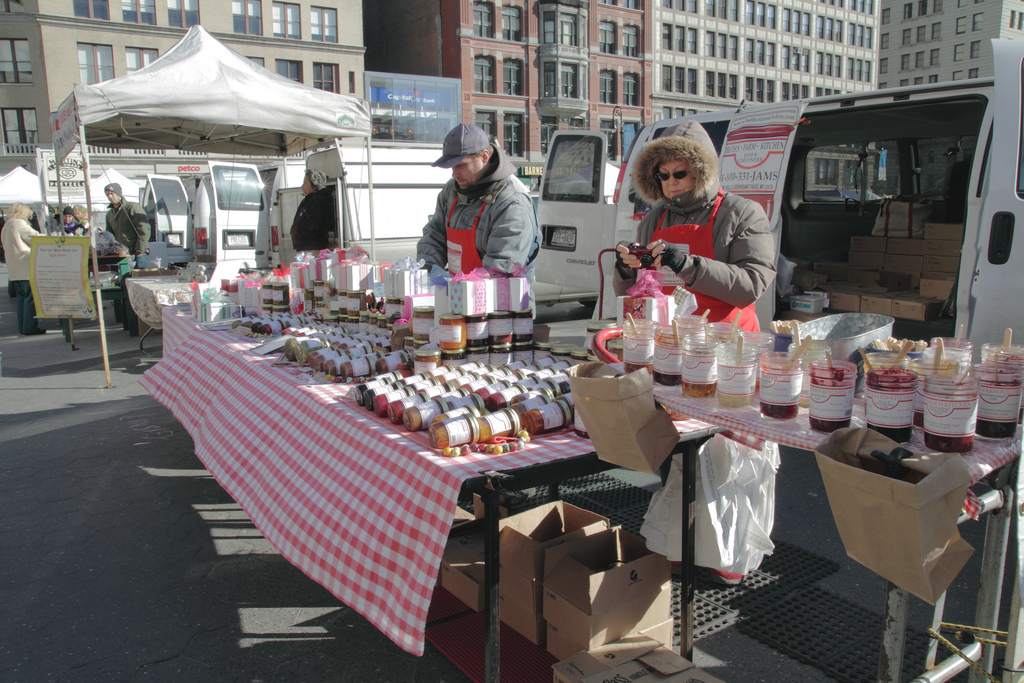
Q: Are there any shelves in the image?
A: No, there are no shelves.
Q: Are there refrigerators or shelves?
A: No, there are no shelves or refrigerators.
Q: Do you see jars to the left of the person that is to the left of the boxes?
A: Yes, there is a jar to the left of the person.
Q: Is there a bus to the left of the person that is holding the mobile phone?
A: No, there is a jar to the left of the person.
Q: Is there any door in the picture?
A: Yes, there is a door.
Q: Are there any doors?
A: Yes, there is a door.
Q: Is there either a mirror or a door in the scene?
A: Yes, there is a door.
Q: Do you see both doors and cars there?
A: No, there is a door but no cars.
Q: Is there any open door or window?
A: Yes, there is an open door.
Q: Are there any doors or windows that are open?
A: Yes, the door is open.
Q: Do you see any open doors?
A: Yes, there is an open door.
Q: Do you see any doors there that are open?
A: Yes, there is a door that is open.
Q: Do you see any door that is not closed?
A: Yes, there is a open door.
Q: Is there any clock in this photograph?
A: No, there are no clocks.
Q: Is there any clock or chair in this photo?
A: No, there are no clocks or chairs.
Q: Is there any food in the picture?
A: Yes, there is food.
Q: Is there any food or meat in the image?
A: Yes, there is food.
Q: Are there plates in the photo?
A: No, there are no plates.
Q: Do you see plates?
A: No, there are no plates.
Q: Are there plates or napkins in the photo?
A: No, there are no plates or napkins.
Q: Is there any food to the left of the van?
A: Yes, there is food to the left of the van.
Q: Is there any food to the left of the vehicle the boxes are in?
A: Yes, there is food to the left of the van.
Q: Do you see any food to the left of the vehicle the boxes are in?
A: Yes, there is food to the left of the van.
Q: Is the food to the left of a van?
A: Yes, the food is to the left of a van.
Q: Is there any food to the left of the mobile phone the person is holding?
A: Yes, there is food to the left of the mobile phone.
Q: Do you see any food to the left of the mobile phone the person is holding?
A: Yes, there is food to the left of the mobile phone.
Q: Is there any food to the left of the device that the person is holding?
A: Yes, there is food to the left of the mobile phone.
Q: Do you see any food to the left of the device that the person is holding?
A: Yes, there is food to the left of the mobile phone.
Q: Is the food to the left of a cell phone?
A: Yes, the food is to the left of a cell phone.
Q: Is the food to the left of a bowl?
A: No, the food is to the left of a cell phone.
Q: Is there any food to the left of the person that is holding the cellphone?
A: Yes, there is food to the left of the person.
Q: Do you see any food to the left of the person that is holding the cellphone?
A: Yes, there is food to the left of the person.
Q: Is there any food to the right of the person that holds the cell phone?
A: No, the food is to the left of the person.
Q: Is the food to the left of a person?
A: Yes, the food is to the left of a person.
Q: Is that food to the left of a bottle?
A: No, the food is to the left of a person.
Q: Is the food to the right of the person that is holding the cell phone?
A: No, the food is to the left of the person.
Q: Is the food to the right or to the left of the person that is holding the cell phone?
A: The food is to the left of the person.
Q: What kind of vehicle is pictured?
A: The vehicle is a van.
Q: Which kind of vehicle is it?
A: The vehicle is a van.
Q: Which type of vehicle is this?
A: This is a van.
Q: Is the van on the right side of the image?
A: Yes, the van is on the right of the image.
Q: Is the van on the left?
A: No, the van is on the right of the image.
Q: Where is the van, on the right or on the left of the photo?
A: The van is on the right of the image.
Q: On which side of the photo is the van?
A: The van is on the right of the image.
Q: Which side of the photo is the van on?
A: The van is on the right of the image.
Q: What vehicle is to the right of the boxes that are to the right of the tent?
A: The vehicle is a van.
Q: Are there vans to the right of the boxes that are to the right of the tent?
A: Yes, there is a van to the right of the boxes.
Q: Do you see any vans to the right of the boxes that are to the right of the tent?
A: Yes, there is a van to the right of the boxes.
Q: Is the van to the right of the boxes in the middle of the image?
A: Yes, the van is to the right of the boxes.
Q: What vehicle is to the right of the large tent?
A: The vehicle is a van.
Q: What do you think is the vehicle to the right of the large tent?
A: The vehicle is a van.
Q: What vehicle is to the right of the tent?
A: The vehicle is a van.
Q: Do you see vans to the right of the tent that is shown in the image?
A: Yes, there is a van to the right of the tent.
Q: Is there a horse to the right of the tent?
A: No, there is a van to the right of the tent.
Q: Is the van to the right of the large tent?
A: Yes, the van is to the right of the tent.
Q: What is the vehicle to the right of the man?
A: The vehicle is a van.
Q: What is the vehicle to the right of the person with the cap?
A: The vehicle is a van.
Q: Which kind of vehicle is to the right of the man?
A: The vehicle is a van.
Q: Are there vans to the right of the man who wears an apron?
A: Yes, there is a van to the right of the man.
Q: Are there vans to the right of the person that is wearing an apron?
A: Yes, there is a van to the right of the man.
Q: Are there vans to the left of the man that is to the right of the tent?
A: No, the van is to the right of the man.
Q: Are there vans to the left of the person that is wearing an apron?
A: No, the van is to the right of the man.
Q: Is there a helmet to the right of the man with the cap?
A: No, there is a van to the right of the man.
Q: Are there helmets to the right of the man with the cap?
A: No, there is a van to the right of the man.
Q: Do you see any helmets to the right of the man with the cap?
A: No, there is a van to the right of the man.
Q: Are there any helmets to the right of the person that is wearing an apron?
A: No, there is a van to the right of the man.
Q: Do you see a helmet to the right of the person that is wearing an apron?
A: No, there is a van to the right of the man.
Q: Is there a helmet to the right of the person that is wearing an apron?
A: No, there is a van to the right of the man.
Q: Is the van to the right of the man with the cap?
A: Yes, the van is to the right of the man.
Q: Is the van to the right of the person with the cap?
A: Yes, the van is to the right of the man.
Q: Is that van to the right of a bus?
A: No, the van is to the right of the man.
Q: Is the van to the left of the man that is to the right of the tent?
A: No, the van is to the right of the man.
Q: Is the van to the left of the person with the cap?
A: No, the van is to the right of the man.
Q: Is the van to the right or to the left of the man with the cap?
A: The van is to the right of the man.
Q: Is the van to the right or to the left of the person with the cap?
A: The van is to the right of the man.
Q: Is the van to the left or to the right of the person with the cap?
A: The van is to the right of the man.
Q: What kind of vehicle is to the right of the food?
A: The vehicle is a van.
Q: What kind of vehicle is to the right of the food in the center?
A: The vehicle is a van.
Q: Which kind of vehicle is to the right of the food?
A: The vehicle is a van.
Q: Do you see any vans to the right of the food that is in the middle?
A: Yes, there is a van to the right of the food.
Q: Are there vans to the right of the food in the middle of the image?
A: Yes, there is a van to the right of the food.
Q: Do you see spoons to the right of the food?
A: No, there is a van to the right of the food.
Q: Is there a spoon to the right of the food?
A: No, there is a van to the right of the food.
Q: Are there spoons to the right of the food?
A: No, there is a van to the right of the food.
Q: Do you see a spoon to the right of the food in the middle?
A: No, there is a van to the right of the food.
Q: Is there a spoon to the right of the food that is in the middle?
A: No, there is a van to the right of the food.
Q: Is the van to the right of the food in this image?
A: Yes, the van is to the right of the food.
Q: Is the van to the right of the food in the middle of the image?
A: Yes, the van is to the right of the food.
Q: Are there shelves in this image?
A: No, there are no shelves.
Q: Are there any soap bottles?
A: No, there are no soap bottles.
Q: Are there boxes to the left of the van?
A: Yes, there are boxes to the left of the van.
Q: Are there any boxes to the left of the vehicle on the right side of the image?
A: Yes, there are boxes to the left of the van.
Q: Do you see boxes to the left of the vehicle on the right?
A: Yes, there are boxes to the left of the van.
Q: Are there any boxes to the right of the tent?
A: Yes, there are boxes to the right of the tent.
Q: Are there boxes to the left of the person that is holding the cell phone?
A: Yes, there are boxes to the left of the person.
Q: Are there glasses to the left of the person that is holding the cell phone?
A: No, there are boxes to the left of the person.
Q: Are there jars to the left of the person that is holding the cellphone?
A: Yes, there is a jar to the left of the person.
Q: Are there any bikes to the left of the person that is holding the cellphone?
A: No, there is a jar to the left of the person.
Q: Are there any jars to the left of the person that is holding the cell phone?
A: Yes, there is a jar to the left of the person.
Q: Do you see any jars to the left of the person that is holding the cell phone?
A: Yes, there is a jar to the left of the person.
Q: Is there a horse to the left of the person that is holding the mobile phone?
A: No, there is a jar to the left of the person.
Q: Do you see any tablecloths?
A: Yes, there is a tablecloth.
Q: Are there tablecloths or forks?
A: Yes, there is a tablecloth.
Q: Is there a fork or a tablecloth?
A: Yes, there is a tablecloth.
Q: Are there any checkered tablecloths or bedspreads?
A: Yes, there is a checkered tablecloth.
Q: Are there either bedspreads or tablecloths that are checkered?
A: Yes, the tablecloth is checkered.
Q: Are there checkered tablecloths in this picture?
A: Yes, there is a checkered tablecloth.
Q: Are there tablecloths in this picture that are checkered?
A: Yes, there is a tablecloth that is checkered.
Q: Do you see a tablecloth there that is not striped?
A: Yes, there is a checkered tablecloth.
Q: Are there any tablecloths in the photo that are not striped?
A: Yes, there is a checkered tablecloth.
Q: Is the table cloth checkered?
A: Yes, the table cloth is checkered.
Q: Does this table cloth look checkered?
A: Yes, the table cloth is checkered.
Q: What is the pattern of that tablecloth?
A: The tablecloth is checkered.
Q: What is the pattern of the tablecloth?
A: The tablecloth is checkered.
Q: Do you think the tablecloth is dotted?
A: No, the tablecloth is checkered.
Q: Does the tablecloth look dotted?
A: No, the tablecloth is checkered.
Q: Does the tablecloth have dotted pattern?
A: No, the tablecloth is checkered.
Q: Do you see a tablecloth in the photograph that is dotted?
A: No, there is a tablecloth but it is checkered.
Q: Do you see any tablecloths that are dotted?
A: No, there is a tablecloth but it is checkered.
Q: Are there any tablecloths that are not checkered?
A: No, there is a tablecloth but it is checkered.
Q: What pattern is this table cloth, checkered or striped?
A: The table cloth is checkered.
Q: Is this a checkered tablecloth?
A: Yes, this is a checkered tablecloth.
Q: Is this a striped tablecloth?
A: No, this is a checkered tablecloth.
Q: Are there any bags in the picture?
A: Yes, there is a bag.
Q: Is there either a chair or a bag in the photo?
A: Yes, there is a bag.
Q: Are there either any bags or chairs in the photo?
A: Yes, there is a bag.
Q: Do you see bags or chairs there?
A: Yes, there is a bag.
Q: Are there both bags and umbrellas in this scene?
A: No, there is a bag but no umbrellas.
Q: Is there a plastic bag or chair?
A: Yes, there is a plastic bag.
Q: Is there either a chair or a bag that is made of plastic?
A: Yes, the bag is made of plastic.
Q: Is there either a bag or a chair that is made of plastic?
A: Yes, the bag is made of plastic.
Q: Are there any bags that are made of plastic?
A: Yes, there is a bag that is made of plastic.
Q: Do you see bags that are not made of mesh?
A: Yes, there is a bag that is made of plastic.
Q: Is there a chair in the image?
A: No, there are no chairs.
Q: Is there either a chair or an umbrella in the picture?
A: No, there are no chairs or umbrellas.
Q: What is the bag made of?
A: The bag is made of plastic.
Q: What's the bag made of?
A: The bag is made of plastic.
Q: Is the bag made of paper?
A: No, the bag is made of plastic.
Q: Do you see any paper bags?
A: No, there is a bag but it is made of plastic.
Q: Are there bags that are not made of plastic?
A: No, there is a bag but it is made of plastic.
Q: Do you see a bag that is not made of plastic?
A: No, there is a bag but it is made of plastic.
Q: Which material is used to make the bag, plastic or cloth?
A: The bag is made of plastic.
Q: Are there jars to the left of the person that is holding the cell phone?
A: Yes, there is a jar to the left of the person.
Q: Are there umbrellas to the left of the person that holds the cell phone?
A: No, there is a jar to the left of the person.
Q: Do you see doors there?
A: Yes, there is a door.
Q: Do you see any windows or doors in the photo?
A: Yes, there is a door.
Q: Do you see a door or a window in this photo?
A: Yes, there is a door.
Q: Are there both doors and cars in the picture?
A: No, there is a door but no cars.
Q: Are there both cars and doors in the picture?
A: No, there is a door but no cars.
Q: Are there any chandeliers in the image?
A: No, there are no chandeliers.